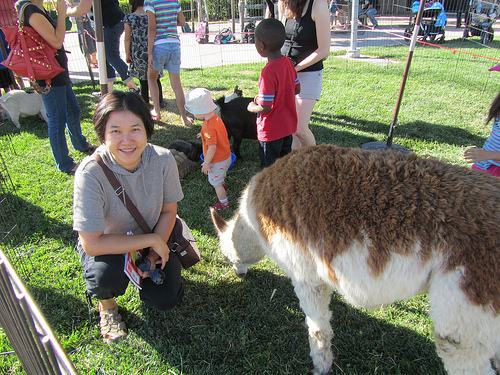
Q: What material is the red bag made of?
A: Leather.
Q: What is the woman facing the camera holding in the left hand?
A: Sunglasses.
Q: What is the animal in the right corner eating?
A: Grass.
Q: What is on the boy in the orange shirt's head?
A: A hat.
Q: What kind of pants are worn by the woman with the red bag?
A: Jeans.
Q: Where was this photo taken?
A: A petting zoo.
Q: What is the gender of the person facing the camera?
A: Female.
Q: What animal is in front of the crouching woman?
A: Goat.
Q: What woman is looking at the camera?
A: The one near the goat.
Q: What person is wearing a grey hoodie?
A: The woman crouching down.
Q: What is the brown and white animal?
A: Goat.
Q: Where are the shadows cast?
A: On the grass.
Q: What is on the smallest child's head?
A: White hat.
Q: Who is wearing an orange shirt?
A: Youngest child.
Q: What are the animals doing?
A: Grazing.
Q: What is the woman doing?
A: Posing for a picture.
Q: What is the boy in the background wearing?
A: A red tee shirt and black pants.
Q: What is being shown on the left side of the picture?
A: A fence.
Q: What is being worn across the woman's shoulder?
A: A brown bag.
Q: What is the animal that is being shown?
A: A sheep.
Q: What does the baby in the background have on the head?
A: A hat.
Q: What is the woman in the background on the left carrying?
A: A big brown bag.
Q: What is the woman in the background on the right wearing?
A: A black tank top and tan shorts.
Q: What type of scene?
A: Outdoor.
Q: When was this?
A: Daytime.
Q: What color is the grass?
A: Green.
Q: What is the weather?
A: Sunny.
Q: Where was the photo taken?
A: Park.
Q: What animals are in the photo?
A: Dogs.